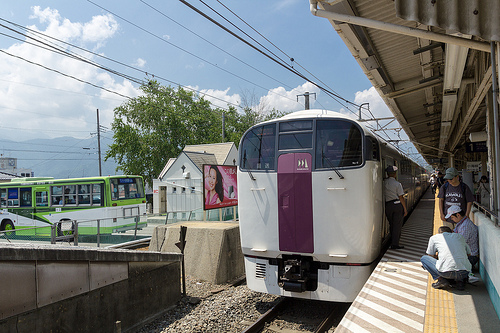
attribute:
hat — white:
[445, 203, 465, 216]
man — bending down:
[444, 205, 481, 268]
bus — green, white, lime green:
[3, 172, 144, 241]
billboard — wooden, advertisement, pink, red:
[199, 155, 243, 210]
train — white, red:
[238, 113, 428, 313]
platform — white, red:
[330, 171, 498, 332]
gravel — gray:
[162, 281, 330, 332]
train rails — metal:
[244, 297, 340, 332]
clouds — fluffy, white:
[1, 15, 408, 164]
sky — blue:
[1, 3, 431, 200]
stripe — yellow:
[424, 175, 459, 333]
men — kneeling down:
[424, 205, 482, 291]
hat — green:
[441, 166, 463, 179]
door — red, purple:
[276, 152, 314, 253]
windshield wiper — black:
[242, 139, 345, 185]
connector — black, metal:
[279, 258, 313, 291]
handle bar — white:
[246, 246, 349, 262]